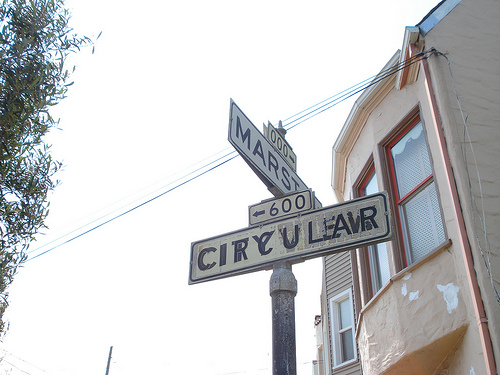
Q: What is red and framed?
A: A window.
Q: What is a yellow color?
A: A building.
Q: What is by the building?
A: Street signs.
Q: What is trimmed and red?
A: Bay windows.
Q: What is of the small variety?
A: Tree branches.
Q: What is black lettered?
A: A sign.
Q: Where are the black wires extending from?
A: The house.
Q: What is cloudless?
A: The sky.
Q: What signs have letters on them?
A: Street signs.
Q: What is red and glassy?
A: The red windows.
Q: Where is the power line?
A: In the sky.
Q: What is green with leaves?
A: The tree.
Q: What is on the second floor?
A: A building.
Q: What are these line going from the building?
A: Power lines.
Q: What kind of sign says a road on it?
A: Road sign.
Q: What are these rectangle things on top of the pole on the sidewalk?
A: Signs.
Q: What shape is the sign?
A: Rectangle.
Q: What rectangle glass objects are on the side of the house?
A: Windows.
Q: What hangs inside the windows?
A: Curtains.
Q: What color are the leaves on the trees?
A: Green.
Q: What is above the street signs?
A: Electrical lines.